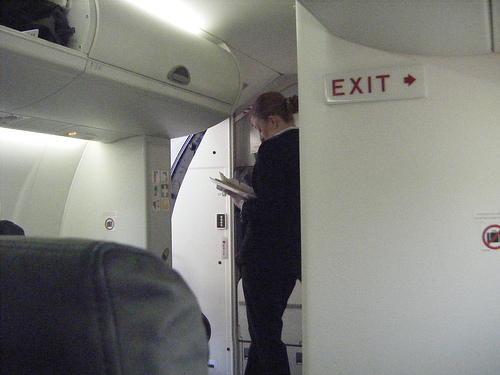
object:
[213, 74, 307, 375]
flight attendant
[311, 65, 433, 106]
sign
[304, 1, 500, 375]
wall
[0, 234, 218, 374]
seat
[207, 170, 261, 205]
papers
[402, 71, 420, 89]
arrow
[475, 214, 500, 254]
sign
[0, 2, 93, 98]
bin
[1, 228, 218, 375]
headrest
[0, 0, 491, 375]
airliner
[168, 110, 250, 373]
boarding door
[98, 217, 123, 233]
sign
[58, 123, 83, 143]
reading lamp